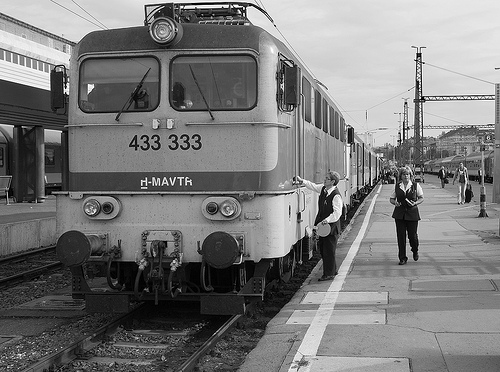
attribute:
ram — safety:
[194, 225, 249, 277]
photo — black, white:
[0, 1, 499, 370]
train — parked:
[50, 0, 395, 314]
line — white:
[309, 277, 341, 351]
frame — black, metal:
[395, 51, 499, 169]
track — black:
[53, 304, 240, 369]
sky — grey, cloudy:
[276, 4, 496, 139]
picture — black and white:
[0, 2, 499, 369]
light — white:
[148, 17, 184, 42]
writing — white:
[139, 170, 193, 193]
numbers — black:
[127, 133, 203, 151]